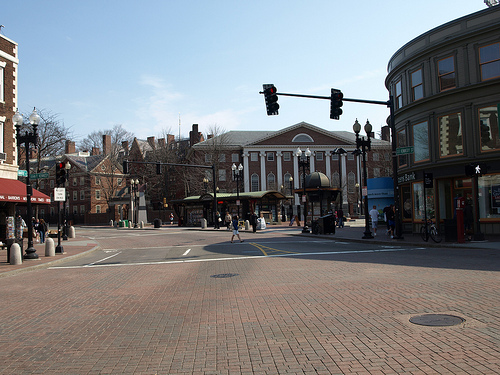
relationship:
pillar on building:
[241, 150, 251, 192] [204, 120, 396, 223]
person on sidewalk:
[35, 216, 50, 246] [30, 221, 75, 241]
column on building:
[241, 160, 254, 185] [218, 124, 399, 243]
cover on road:
[409, 312, 465, 327] [0, 225, 500, 375]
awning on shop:
[0, 176, 52, 203] [0, 163, 52, 242]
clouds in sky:
[130, 64, 196, 105] [135, 32, 250, 84]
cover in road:
[409, 313, 466, 327] [0, 225, 500, 375]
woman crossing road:
[218, 212, 247, 248] [0, 225, 500, 375]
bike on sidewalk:
[417, 217, 442, 245] [287, 224, 497, 251]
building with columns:
[190, 120, 392, 218] [238, 140, 351, 202]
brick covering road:
[262, 350, 272, 357] [2, 221, 484, 371]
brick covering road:
[188, 336, 199, 344] [2, 221, 484, 371]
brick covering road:
[197, 334, 207, 343] [2, 221, 484, 371]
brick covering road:
[396, 340, 411, 349] [2, 221, 484, 371]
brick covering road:
[302, 305, 315, 317] [2, 221, 484, 371]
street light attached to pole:
[9, 105, 25, 125] [24, 132, 38, 261]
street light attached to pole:
[26, 104, 41, 127] [24, 132, 38, 261]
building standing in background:
[376, 5, 498, 240] [2, 3, 483, 268]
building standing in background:
[190, 120, 392, 218] [2, 3, 483, 268]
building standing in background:
[14, 134, 134, 221] [2, 3, 483, 268]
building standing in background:
[0, 32, 52, 256] [2, 3, 483, 268]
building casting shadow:
[382, 4, 483, 241] [200, 222, 495, 280]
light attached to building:
[239, 70, 366, 133] [382, 4, 483, 241]